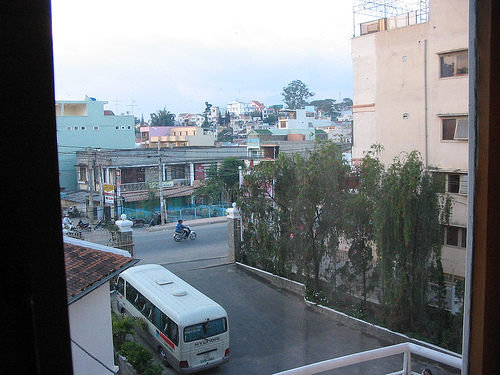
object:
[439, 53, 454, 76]
window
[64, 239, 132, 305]
roofing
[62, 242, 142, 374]
building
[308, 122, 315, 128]
window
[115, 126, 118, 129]
window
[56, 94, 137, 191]
building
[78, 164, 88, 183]
window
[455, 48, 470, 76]
window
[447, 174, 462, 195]
window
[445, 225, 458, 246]
window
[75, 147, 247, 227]
building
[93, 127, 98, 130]
window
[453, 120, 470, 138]
window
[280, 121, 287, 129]
window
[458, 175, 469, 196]
window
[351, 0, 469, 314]
building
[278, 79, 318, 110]
trees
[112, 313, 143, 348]
trees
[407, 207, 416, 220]
leaves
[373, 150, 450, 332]
trees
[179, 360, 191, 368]
lights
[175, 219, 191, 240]
person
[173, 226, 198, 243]
motorbike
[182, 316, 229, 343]
windows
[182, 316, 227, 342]
back window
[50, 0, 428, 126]
sky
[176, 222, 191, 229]
coat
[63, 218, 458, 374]
road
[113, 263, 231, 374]
bus